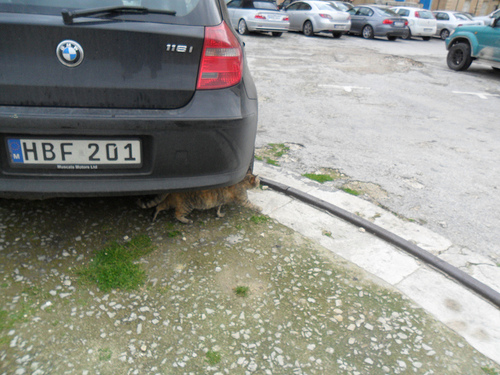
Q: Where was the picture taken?
A: It was taken at the parking lot.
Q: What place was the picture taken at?
A: It was taken at the parking lot.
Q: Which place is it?
A: It is a parking lot.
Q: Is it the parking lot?
A: Yes, it is the parking lot.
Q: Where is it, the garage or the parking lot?
A: It is the parking lot.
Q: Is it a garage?
A: No, it is a parking lot.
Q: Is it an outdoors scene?
A: Yes, it is outdoors.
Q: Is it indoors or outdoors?
A: It is outdoors.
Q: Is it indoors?
A: No, it is outdoors.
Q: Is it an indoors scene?
A: No, it is outdoors.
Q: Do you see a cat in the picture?
A: Yes, there is a cat.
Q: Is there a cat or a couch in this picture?
A: Yes, there is a cat.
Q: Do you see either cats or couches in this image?
A: Yes, there is a cat.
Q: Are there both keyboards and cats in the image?
A: No, there is a cat but no keyboards.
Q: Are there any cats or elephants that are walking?
A: Yes, the cat is walking.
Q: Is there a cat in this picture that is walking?
A: Yes, there is a cat that is walking.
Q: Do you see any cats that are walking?
A: Yes, there is a cat that is walking.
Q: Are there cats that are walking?
A: Yes, there is a cat that is walking.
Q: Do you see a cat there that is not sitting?
A: Yes, there is a cat that is walking .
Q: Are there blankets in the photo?
A: No, there are no blankets.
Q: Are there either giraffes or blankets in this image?
A: No, there are no blankets or giraffes.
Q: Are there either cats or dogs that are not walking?
A: No, there is a cat but it is walking.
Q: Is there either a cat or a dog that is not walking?
A: No, there is a cat but it is walking.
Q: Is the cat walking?
A: Yes, the cat is walking.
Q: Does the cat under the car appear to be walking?
A: Yes, the cat is walking.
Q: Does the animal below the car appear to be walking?
A: Yes, the cat is walking.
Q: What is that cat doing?
A: The cat is walking.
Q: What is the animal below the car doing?
A: The cat is walking.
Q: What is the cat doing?
A: The cat is walking.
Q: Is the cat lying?
A: No, the cat is walking.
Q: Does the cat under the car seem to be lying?
A: No, the cat is walking.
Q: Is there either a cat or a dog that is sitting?
A: No, there is a cat but it is walking.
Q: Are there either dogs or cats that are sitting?
A: No, there is a cat but it is walking.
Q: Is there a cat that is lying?
A: No, there is a cat but it is walking.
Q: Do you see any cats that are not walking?
A: No, there is a cat but it is walking.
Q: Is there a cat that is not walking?
A: No, there is a cat but it is walking.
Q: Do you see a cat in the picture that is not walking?
A: No, there is a cat but it is walking.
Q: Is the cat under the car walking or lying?
A: The cat is walking.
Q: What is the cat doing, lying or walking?
A: The cat is walking.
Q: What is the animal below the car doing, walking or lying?
A: The cat is walking.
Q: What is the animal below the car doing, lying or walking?
A: The cat is walking.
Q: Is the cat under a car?
A: Yes, the cat is under a car.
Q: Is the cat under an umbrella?
A: No, the cat is under a car.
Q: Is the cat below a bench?
A: No, the cat is below a car.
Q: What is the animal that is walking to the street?
A: The animal is a cat.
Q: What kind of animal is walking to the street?
A: The animal is a cat.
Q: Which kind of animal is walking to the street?
A: The animal is a cat.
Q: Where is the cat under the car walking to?
A: The cat is walking to the street.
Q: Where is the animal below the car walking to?
A: The cat is walking to the street.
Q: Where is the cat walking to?
A: The cat is walking to the street.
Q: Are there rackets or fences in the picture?
A: No, there are no fences or rackets.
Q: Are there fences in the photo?
A: No, there are no fences.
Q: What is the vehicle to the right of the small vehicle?
A: The vehicle is a car.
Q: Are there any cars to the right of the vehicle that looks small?
A: Yes, there is a car to the right of the vehicle.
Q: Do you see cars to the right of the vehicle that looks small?
A: Yes, there is a car to the right of the vehicle.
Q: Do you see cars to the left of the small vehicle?
A: No, the car is to the right of the vehicle.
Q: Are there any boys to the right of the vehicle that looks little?
A: No, there is a car to the right of the vehicle.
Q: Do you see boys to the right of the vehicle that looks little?
A: No, there is a car to the right of the vehicle.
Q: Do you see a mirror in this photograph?
A: No, there are no mirrors.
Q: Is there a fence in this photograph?
A: No, there are no fences.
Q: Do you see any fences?
A: No, there are no fences.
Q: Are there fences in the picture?
A: No, there are no fences.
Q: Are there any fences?
A: No, there are no fences.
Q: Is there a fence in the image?
A: No, there are no fences.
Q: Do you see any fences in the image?
A: No, there are no fences.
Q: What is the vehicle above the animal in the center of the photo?
A: The vehicle is a car.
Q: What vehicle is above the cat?
A: The vehicle is a car.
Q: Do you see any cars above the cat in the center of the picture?
A: Yes, there is a car above the cat.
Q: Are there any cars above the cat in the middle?
A: Yes, there is a car above the cat.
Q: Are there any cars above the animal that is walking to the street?
A: Yes, there is a car above the cat.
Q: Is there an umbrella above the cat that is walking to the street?
A: No, there is a car above the cat.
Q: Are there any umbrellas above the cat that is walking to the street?
A: No, there is a car above the cat.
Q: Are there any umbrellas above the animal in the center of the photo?
A: No, there is a car above the cat.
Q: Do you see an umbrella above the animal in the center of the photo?
A: No, there is a car above the cat.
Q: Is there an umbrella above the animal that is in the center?
A: No, there is a car above the cat.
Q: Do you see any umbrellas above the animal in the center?
A: No, there is a car above the cat.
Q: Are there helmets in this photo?
A: No, there are no helmets.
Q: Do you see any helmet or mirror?
A: No, there are no helmets or mirrors.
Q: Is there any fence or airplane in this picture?
A: No, there are no fences or airplanes.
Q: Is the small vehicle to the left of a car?
A: Yes, the vehicle is to the left of a car.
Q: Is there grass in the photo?
A: Yes, there is grass.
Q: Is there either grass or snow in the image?
A: Yes, there is grass.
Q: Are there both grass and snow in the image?
A: No, there is grass but no snow.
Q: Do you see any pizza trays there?
A: No, there are no pizza trays.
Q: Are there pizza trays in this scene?
A: No, there are no pizza trays.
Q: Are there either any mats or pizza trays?
A: No, there are no pizza trays or mats.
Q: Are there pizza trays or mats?
A: No, there are no pizza trays or mats.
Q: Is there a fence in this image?
A: No, there are no fences.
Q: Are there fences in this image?
A: No, there are no fences.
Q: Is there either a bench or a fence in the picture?
A: No, there are no fences or benches.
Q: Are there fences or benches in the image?
A: No, there are no fences or benches.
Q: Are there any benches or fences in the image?
A: No, there are no fences or benches.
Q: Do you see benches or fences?
A: No, there are no fences or benches.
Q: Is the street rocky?
A: Yes, the street is rocky.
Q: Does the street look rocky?
A: Yes, the street is rocky.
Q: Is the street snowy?
A: No, the street is rocky.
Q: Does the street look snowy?
A: No, the street is rocky.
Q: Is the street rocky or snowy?
A: The street is rocky.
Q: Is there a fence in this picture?
A: No, there are no fences.